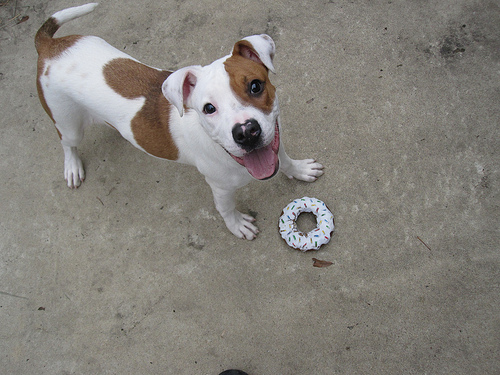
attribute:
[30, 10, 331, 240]
puppy — white , brown 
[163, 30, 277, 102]
ears — droppy 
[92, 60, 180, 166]
spots — brown 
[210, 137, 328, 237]
paws — white 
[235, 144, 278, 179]
tongue — pink 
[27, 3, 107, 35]
tail — white 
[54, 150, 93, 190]
paw — white 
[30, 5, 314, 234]
dog — white , brown 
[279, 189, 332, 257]
treat — dog 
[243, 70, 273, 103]
eye — canine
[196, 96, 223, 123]
eye — canine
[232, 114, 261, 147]
nose — canine, one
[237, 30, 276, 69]
ear — one, canine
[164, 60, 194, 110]
ear — canine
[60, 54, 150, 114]
fur — canine, brown , white 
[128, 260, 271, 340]
surface — cement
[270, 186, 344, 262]
frosting — white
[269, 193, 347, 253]
frosting — white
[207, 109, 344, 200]
mouth — open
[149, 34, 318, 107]
ears — folded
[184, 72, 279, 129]
eyes — dark, brown, dog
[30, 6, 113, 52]
tail — dog, brown, white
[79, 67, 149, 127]
fur — white, brown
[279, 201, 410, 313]
toy — shaped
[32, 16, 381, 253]
dog — white, brown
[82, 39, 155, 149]
spot — brown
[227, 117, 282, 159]
nose — black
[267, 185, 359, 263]
toy — dog